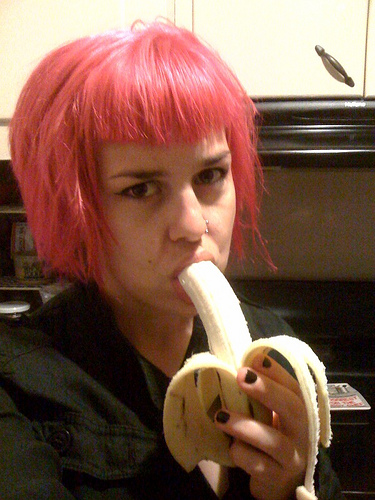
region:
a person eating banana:
[2, 17, 328, 495]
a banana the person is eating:
[161, 262, 333, 498]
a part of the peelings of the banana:
[284, 335, 333, 498]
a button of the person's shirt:
[45, 427, 69, 453]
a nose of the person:
[167, 179, 209, 243]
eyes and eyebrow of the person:
[107, 149, 232, 201]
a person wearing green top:
[1, 22, 337, 497]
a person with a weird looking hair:
[1, 18, 343, 495]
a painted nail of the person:
[245, 369, 257, 383]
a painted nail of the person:
[215, 411, 230, 423]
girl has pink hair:
[37, 14, 291, 296]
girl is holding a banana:
[194, 357, 327, 491]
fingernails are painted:
[189, 352, 285, 431]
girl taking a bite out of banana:
[175, 247, 222, 280]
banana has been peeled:
[167, 333, 339, 499]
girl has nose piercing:
[193, 215, 211, 236]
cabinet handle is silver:
[294, 42, 352, 89]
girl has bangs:
[86, 99, 260, 159]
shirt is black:
[13, 279, 190, 497]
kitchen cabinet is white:
[239, 4, 338, 48]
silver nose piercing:
[195, 210, 214, 240]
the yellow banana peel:
[130, 328, 333, 493]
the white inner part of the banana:
[160, 242, 251, 362]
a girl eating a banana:
[8, 15, 366, 485]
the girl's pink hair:
[7, 19, 292, 294]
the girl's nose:
[163, 180, 214, 249]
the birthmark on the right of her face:
[139, 251, 157, 272]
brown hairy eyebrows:
[105, 148, 233, 186]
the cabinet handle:
[308, 25, 365, 91]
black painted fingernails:
[207, 349, 281, 456]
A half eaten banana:
[165, 263, 332, 462]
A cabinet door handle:
[313, 44, 357, 86]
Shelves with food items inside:
[0, 158, 107, 318]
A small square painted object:
[325, 380, 372, 407]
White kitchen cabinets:
[3, 4, 373, 100]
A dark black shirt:
[1, 281, 339, 499]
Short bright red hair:
[11, 32, 270, 279]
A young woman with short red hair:
[2, 26, 342, 486]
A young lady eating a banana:
[1, 19, 343, 498]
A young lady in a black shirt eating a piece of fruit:
[1, 26, 355, 499]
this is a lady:
[18, 26, 253, 269]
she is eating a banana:
[157, 271, 292, 439]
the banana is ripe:
[184, 273, 240, 355]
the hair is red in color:
[40, 53, 106, 114]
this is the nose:
[175, 213, 207, 237]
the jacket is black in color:
[79, 365, 134, 450]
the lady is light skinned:
[122, 210, 162, 244]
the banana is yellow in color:
[210, 276, 227, 301]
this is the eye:
[119, 177, 161, 200]